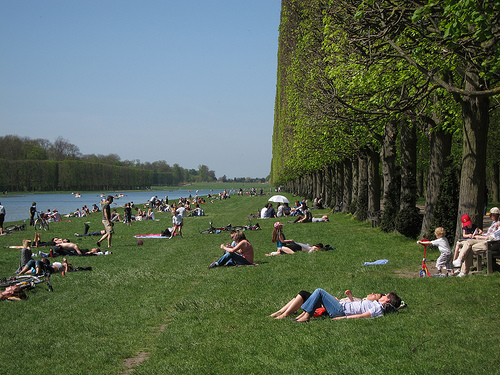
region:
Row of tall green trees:
[278, 7, 485, 221]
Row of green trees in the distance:
[1, 134, 217, 188]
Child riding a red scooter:
[415, 226, 453, 281]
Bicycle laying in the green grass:
[7, 262, 53, 303]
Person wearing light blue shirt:
[190, 200, 205, 218]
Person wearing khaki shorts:
[100, 216, 116, 234]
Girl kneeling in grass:
[270, 220, 289, 259]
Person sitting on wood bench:
[454, 205, 497, 275]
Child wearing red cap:
[457, 212, 472, 229]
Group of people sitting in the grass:
[62, 202, 100, 219]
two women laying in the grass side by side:
[264, 285, 404, 322]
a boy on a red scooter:
[413, 225, 455, 279]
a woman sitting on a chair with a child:
[454, 203, 498, 279]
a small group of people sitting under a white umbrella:
[255, 193, 292, 218]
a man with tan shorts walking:
[94, 193, 116, 248]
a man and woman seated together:
[204, 232, 257, 272]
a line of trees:
[2, 155, 177, 192]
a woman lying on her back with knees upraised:
[12, 254, 93, 274]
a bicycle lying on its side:
[199, 219, 256, 234]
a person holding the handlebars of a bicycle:
[27, 200, 51, 232]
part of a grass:
[342, 322, 369, 337]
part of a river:
[63, 190, 81, 205]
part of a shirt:
[363, 300, 368, 308]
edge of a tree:
[338, 147, 358, 166]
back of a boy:
[441, 247, 453, 263]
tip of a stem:
[418, 149, 465, 254]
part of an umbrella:
[280, 193, 283, 198]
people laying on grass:
[268, 279, 408, 328]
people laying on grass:
[206, 230, 262, 275]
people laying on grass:
[147, 218, 187, 244]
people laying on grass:
[297, 204, 334, 224]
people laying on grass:
[56, 243, 98, 262]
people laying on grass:
[43, 260, 84, 275]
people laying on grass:
[188, 205, 208, 217]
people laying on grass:
[137, 208, 167, 225]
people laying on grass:
[268, 202, 295, 216]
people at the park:
[75, 163, 445, 345]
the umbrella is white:
[259, 178, 314, 216]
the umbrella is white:
[265, 193, 296, 203]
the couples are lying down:
[256, 271, 458, 338]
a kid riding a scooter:
[416, 214, 453, 281]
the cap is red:
[454, 212, 479, 234]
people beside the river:
[16, 168, 151, 239]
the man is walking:
[90, 189, 121, 264]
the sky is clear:
[42, 27, 167, 142]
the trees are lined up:
[30, 137, 409, 232]